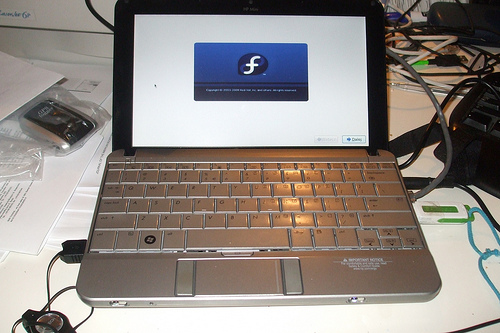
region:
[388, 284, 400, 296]
part of a laptop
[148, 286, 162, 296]
edge of a laptop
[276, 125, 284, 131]
part of a screen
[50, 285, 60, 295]
part of a cable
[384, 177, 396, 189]
edge of a laptop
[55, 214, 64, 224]
part of a paper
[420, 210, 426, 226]
part of a modem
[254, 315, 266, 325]
part of a table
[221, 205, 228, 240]
part of a mouse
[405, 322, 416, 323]
side of a table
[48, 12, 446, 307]
this is a laptop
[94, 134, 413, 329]
the laptop is silver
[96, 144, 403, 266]
the keyboard is silver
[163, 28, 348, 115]
this is a facebook logo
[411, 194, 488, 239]
this is a flash drive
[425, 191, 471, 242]
the flash drive is green and white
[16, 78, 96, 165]
this is a mouse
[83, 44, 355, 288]
this is a windows computer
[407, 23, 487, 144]
these are a bunch of wires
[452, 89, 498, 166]
this is a phone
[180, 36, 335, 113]
a blue area on a laptop screen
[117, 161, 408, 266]
a grey keyboard on a laptop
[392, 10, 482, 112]
wires in the back of a laptop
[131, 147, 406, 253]
key on a keyboard of a laptop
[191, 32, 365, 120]
a white f on the screen of a laptop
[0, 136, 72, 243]
paper with typed words on the side of a laptop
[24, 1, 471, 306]
a laptop sitting on a table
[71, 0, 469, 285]
a black and grey laptop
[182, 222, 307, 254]
the space bar on a laptop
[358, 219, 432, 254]
the arrow keys on a laptop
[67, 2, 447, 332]
The laptop is open and powered on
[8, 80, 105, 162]
A device wrapped in plastic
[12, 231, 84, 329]
something is plugged into the laptop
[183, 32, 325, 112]
a blue box with an f icon on the screen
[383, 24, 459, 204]
ethernet cable plugged into computer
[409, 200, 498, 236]
there is a flash drive plugged into computer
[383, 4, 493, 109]
A bundle of wires behind the laptop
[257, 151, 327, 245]
Orange glow on some of the keys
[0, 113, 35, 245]
Papers sit next to computer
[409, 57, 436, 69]
bright green marker on usb cable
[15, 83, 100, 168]
A cell phone in a package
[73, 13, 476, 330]
A cell phone on the desk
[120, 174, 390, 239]
The keyboard on the desk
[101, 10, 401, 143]
The screen to the laptop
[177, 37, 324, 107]
A logo on the screen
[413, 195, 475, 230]
A USB cord plugged in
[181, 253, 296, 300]
the mouse pad on the laptop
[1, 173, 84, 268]
Paperwork on the desk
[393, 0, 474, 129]
Various cords on the desk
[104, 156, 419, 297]
The keyboard is the color gray